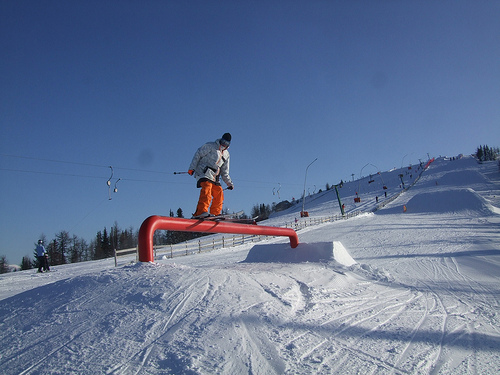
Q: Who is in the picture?
A: The skier.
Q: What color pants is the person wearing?
A: Orange.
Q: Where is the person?
A: On the rail.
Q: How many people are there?
A: One.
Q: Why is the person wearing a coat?
A: It is cold.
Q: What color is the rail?
A: Red.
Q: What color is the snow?
A: White.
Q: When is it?
A: Day time.